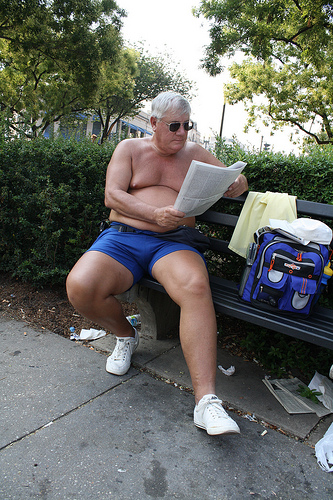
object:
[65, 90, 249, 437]
man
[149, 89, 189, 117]
hair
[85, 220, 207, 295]
shorts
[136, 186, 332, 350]
bench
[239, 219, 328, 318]
bag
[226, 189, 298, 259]
shirt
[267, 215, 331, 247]
cap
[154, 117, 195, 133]
sunglasses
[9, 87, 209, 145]
building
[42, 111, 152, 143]
awnings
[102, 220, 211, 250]
fanny pack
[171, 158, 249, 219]
newspaper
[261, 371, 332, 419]
newspaper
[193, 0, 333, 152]
trees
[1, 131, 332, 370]
bushes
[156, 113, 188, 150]
face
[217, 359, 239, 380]
trash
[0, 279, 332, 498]
pavement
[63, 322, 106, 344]
trash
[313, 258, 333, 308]
water bottle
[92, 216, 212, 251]
waist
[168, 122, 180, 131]
eyes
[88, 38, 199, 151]
trees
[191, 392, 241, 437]
foot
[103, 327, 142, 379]
foot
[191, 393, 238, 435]
tennis shoe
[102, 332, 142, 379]
tennis shoe